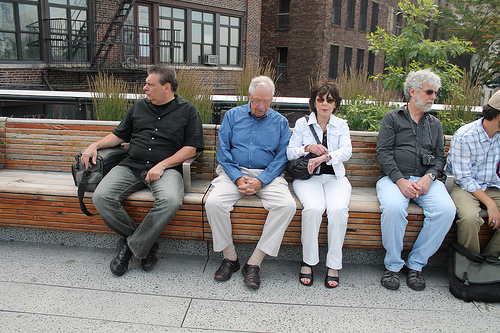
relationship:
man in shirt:
[79, 62, 211, 274] [115, 95, 207, 170]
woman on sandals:
[285, 82, 353, 289] [291, 255, 343, 287]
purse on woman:
[287, 108, 327, 183] [285, 82, 353, 289]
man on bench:
[79, 62, 205, 278] [0, 115, 497, 270]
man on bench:
[197, 72, 294, 284] [0, 115, 497, 270]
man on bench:
[376, 67, 457, 290] [0, 115, 497, 270]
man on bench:
[444, 89, 500, 276] [0, 115, 497, 270]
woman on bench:
[286, 78, 358, 288] [0, 117, 498, 249]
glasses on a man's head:
[423, 88, 438, 96] [403, 70, 440, 117]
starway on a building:
[43, 5, 173, 89] [0, 2, 264, 91]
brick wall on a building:
[95, 1, 151, 59] [25, 7, 284, 105]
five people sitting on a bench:
[81, 61, 484, 291] [306, 180, 393, 237]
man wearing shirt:
[79, 62, 205, 278] [101, 92, 210, 174]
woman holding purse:
[285, 82, 353, 289] [283, 149, 317, 179]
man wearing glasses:
[376, 67, 457, 291] [419, 85, 444, 99]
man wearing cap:
[449, 97, 499, 274] [473, 88, 499, 112]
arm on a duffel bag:
[79, 102, 134, 167] [71, 143, 131, 217]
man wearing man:
[204, 75, 297, 289] [79, 62, 205, 278]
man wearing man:
[204, 75, 297, 289] [376, 67, 457, 290]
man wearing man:
[204, 75, 297, 289] [448, 85, 499, 256]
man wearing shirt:
[204, 75, 297, 289] [215, 97, 290, 187]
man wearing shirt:
[204, 75, 297, 289] [376, 109, 445, 177]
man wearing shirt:
[204, 75, 297, 289] [445, 118, 498, 193]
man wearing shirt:
[204, 75, 297, 289] [114, 98, 205, 173]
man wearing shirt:
[204, 75, 297, 289] [284, 113, 354, 173]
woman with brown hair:
[285, 82, 353, 289] [302, 78, 344, 113]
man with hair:
[376, 67, 457, 290] [399, 67, 441, 91]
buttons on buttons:
[155, 117, 160, 122] [151, 126, 159, 133]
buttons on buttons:
[155, 117, 160, 122] [145, 147, 153, 152]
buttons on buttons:
[155, 117, 160, 122] [145, 159, 152, 166]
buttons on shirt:
[155, 117, 160, 122] [106, 96, 206, 173]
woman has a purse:
[285, 82, 353, 289] [286, 113, 323, 178]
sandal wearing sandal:
[322, 256, 345, 293] [292, 262, 314, 286]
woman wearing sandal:
[285, 82, 353, 289] [292, 262, 314, 286]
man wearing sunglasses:
[376, 67, 457, 290] [416, 87, 435, 96]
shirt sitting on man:
[94, 89, 214, 180] [79, 62, 205, 278]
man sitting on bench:
[79, 62, 205, 278] [4, 95, 496, 265]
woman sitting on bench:
[286, 78, 358, 288] [2, 117, 478, 259]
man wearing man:
[79, 62, 205, 278] [197, 72, 294, 284]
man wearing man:
[79, 62, 205, 278] [370, 62, 459, 295]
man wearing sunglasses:
[79, 62, 205, 278] [314, 94, 338, 105]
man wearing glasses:
[79, 62, 205, 278] [419, 87, 440, 96]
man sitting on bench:
[376, 67, 457, 290] [203, 125, 453, 251]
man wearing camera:
[376, 67, 457, 290] [418, 154, 435, 166]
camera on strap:
[418, 154, 435, 166] [406, 105, 436, 150]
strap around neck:
[406, 105, 436, 150] [404, 97, 421, 124]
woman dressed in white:
[285, 82, 353, 289] [285, 112, 351, 270]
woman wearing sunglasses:
[285, 82, 353, 289] [312, 96, 337, 106]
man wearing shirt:
[204, 75, 297, 289] [217, 105, 294, 183]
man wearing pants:
[204, 75, 297, 289] [207, 163, 295, 255]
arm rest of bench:
[180, 145, 203, 192] [0, 116, 217, 237]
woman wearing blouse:
[285, 82, 353, 289] [288, 111, 348, 172]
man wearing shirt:
[376, 67, 457, 290] [373, 104, 447, 183]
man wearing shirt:
[444, 89, 500, 276] [445, 118, 498, 193]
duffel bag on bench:
[69, 140, 128, 217] [0, 117, 498, 249]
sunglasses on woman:
[315, 97, 335, 102] [285, 82, 353, 289]